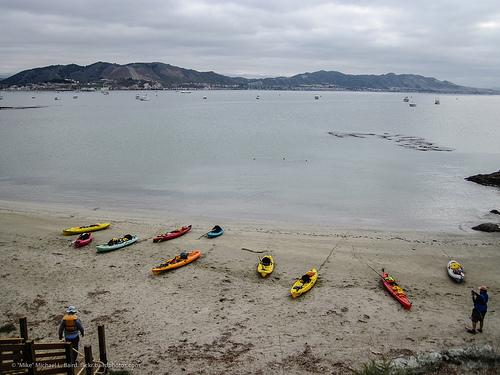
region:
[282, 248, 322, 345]
yellow kayak on beach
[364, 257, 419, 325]
red kayak on beach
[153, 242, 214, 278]
orange kayak on beach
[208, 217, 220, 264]
blue kayak on beach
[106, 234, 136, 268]
teal kayak on beach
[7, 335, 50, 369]
wooden rail leading to beach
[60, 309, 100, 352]
man wearing orange vest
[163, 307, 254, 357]
sand covered by seaweed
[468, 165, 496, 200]
black rock in ocean water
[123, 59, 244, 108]
large green hills in distance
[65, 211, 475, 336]
Little boats on the water.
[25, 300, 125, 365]
Man near a set of shairs.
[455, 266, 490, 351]
A man standing on the beach.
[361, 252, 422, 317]
A little red boat.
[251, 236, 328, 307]
Two little yellow boats.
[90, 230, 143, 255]
A light blue boat.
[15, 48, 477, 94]
Mountains in the distance.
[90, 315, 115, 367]
A wood pole.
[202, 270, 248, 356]
Imprints in the sand.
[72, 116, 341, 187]
Water in the ocean.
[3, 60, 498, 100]
mountains in background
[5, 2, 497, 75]
dark clouds over mountains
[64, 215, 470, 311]
beached kayaks near water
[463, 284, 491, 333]
man standing on beach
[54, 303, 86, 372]
man in life jacket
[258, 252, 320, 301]
two yellow kayaks on beach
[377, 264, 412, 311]
red kayak on shore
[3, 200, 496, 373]
sandy beach with kayaks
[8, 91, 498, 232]
water between mountains and beach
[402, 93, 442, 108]
boats in water in distance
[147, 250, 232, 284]
orange and black kayak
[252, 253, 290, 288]
yellow kayak on the beach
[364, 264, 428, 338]
red and yellow kayak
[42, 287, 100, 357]
person wearing life jacket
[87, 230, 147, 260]
blue colored kayak on sand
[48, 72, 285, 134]
boats out in the water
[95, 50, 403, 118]
mountains in the distance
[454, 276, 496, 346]
person standing on the sand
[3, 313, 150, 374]
wood building on beach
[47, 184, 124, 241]
yellow kayak near water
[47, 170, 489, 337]
kayaks on the beach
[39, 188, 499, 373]
kayaks on the sand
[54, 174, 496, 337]
different color kayaks on the beach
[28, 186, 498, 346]
different color kayaks on sand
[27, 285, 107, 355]
a man with life vest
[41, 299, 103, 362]
a man with life jacket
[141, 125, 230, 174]
a body of water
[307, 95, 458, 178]
a patch of sand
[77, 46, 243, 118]
mountains in the distance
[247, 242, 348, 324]
two yellow kayaks